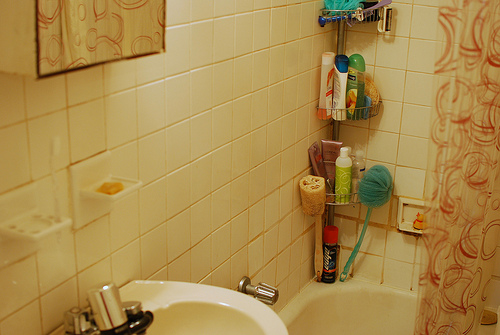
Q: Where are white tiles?
A: On the wall.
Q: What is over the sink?
A: A faucet.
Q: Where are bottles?
A: On a rack.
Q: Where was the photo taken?
A: In a bathroom.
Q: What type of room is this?
A: Bathroom.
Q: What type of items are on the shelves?
A: Toiletries.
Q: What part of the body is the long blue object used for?
A: Back.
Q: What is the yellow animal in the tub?
A: Duck.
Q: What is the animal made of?
A: Rubber.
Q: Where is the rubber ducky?
A: Soap dish.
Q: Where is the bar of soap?
A: Soap dish.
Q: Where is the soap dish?
A: Above sink.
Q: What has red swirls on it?
A: Shower curtain.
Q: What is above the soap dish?
A: Medicine cabinet.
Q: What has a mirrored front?
A: The metal medicine cabinet.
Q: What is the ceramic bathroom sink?
A: White.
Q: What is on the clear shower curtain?
A: Red swirl design.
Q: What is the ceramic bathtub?
A: White.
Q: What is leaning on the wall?
A: The loofah.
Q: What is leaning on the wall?
A: The loofah.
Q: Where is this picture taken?
A: A bathroom.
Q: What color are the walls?
A: Cream.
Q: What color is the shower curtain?
A: Red.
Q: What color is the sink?
A: White.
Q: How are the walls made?
A: Of tile.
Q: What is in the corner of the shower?
A: Toiletries.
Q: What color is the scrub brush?
A: Aqua.